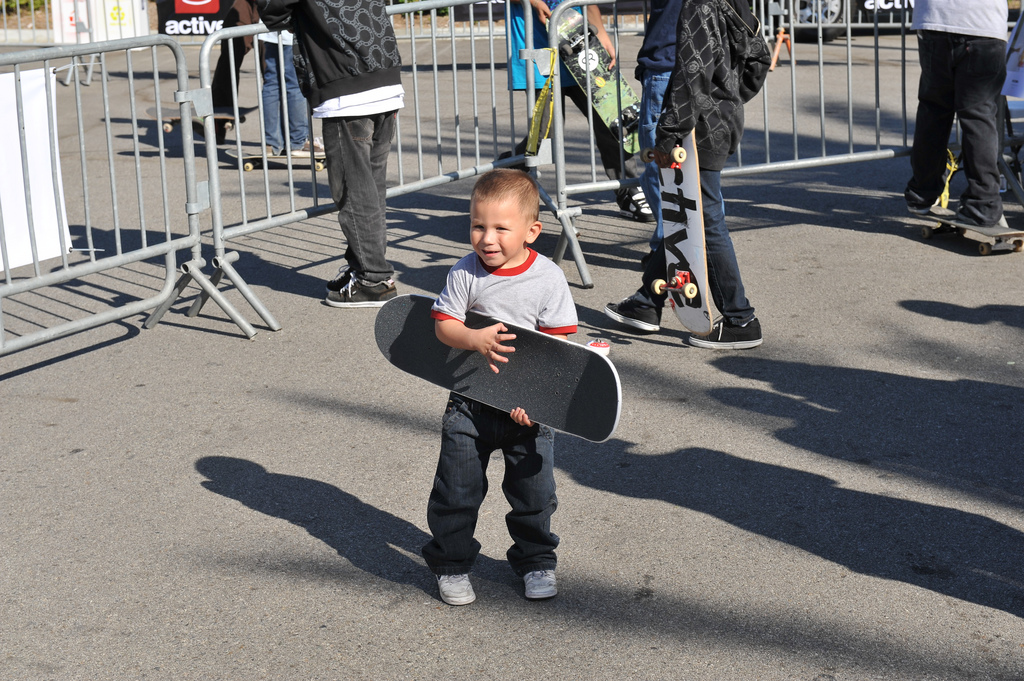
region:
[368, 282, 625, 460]
Boy holding a board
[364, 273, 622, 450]
Boy holding a skateboard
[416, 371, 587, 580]
Boy wearing blue pants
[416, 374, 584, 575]
Boy is wearing blue pants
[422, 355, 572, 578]
Boy wearing blue jeans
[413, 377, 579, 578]
Boy is wearing blue jeans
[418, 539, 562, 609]
Boy wearing white shoes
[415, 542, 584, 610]
Boy is wearing white shoes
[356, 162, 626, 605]
little boy is holding a skateboard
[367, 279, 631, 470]
skateboard is black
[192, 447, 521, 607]
shadow is from the little boy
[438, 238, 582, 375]
gray and red shirt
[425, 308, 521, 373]
arm is over the skateboard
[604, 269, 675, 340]
black and white shoe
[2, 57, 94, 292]
sign is on the fence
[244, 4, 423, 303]
person is hanging over the fence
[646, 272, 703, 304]
white wheels are under the skateboard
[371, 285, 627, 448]
A black skateboard.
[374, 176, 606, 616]
A young boy holding a skateboard.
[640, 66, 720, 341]
A white skateboard with black lettering.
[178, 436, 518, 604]
The shadow of a little boy.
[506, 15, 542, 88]
A pair of bright blue shorts.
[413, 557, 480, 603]
A white sneaker on a little boy.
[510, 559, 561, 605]
A white sneaker on a little boy.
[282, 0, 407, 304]
A person leaning on a fence.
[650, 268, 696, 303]
white wheels on a black and white skateboard.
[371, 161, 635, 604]
little boy holding a skateboard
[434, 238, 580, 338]
red and gray shirt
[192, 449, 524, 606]
shadow from the little boy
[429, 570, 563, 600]
a pair of white shoes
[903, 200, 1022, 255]
skateboard is on the ground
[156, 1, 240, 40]
red, white, and black sign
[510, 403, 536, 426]
fingers curled over the bottom of the skateboard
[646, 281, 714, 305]
white wheels on the bottom of the skateboard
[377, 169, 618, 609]
a boy holding a skateboard in his hands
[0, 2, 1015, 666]
gray metal fences on the street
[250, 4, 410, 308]
man standing next to a fence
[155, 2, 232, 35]
a black, red and white sign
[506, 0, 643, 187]
person with blue shorts holding a skateboard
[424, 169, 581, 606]
boy with short blond hair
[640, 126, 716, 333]
skateboard with yellow wheels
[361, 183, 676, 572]
a boy holding a skateboard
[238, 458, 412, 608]
a shadow on the ground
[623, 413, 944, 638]
a shadow on the ground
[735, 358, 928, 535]
a shadow on the ground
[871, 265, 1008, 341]
a shadow on the ground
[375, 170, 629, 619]
boy in gray shirt holding skateboard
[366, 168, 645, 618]
boy in gray shirt holding skateboard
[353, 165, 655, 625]
boy in gray shirt holding skateboard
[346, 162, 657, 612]
boy in gray shirt holding skateboard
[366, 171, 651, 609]
boy in gray shirt holding skateboard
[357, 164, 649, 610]
boy in gray shirt holding skateboard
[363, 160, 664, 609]
boy in gray shirt holding skateboard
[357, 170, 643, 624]
boy in gray shirt holding skateboard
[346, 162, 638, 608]
boy in gray shirt holding skateboard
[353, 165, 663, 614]
boy in gray shirt holding skateboard